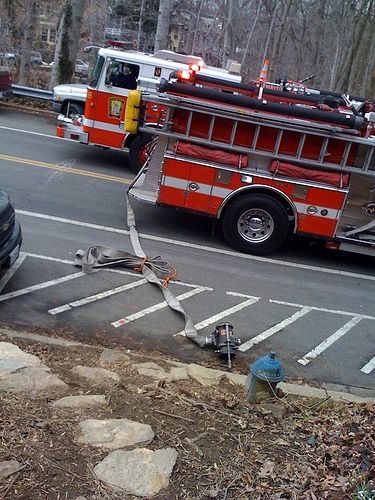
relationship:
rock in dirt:
[89, 445, 177, 498] [1, 333, 371, 499]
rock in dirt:
[73, 415, 153, 449] [1, 333, 371, 499]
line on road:
[1, 153, 133, 185] [2, 124, 368, 283]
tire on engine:
[217, 192, 290, 258] [121, 67, 371, 257]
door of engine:
[87, 56, 142, 153] [55, 41, 375, 177]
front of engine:
[53, 45, 104, 151] [55, 41, 375, 177]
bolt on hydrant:
[268, 346, 278, 360] [245, 349, 289, 409]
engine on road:
[121, 67, 371, 257] [2, 124, 368, 283]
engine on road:
[55, 41, 375, 177] [2, 124, 368, 283]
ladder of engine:
[130, 90, 375, 177] [121, 67, 371, 257]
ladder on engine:
[130, 90, 375, 177] [121, 67, 371, 257]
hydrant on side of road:
[245, 349, 289, 409] [2, 124, 368, 283]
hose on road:
[72, 144, 210, 350] [2, 124, 368, 283]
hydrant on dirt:
[245, 349, 289, 409] [1, 333, 371, 499]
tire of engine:
[217, 192, 290, 258] [121, 67, 371, 257]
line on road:
[10, 205, 374, 280] [2, 124, 368, 283]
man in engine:
[108, 65, 139, 92] [55, 41, 375, 177]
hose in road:
[72, 144, 210, 350] [2, 124, 368, 283]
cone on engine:
[258, 56, 271, 85] [55, 41, 375, 177]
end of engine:
[119, 65, 179, 203] [121, 67, 371, 257]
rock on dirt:
[89, 445, 177, 498] [1, 333, 371, 499]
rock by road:
[89, 445, 177, 498] [2, 124, 368, 283]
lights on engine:
[175, 62, 207, 81] [121, 67, 371, 257]